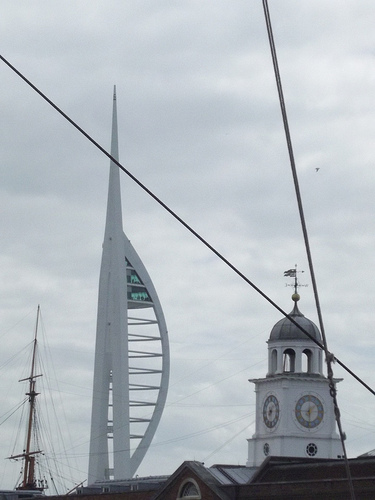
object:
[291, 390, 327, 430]
clock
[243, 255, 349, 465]
tower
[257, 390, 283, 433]
clock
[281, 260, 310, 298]
vane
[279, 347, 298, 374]
arch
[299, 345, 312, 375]
arch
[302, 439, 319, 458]
circle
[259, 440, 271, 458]
circle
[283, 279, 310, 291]
arrow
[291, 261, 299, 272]
point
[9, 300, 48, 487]
mast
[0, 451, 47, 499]
boat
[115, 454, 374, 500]
building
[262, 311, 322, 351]
dome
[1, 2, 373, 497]
sky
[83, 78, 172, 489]
statue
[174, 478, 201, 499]
window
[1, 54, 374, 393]
wires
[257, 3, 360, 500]
wires